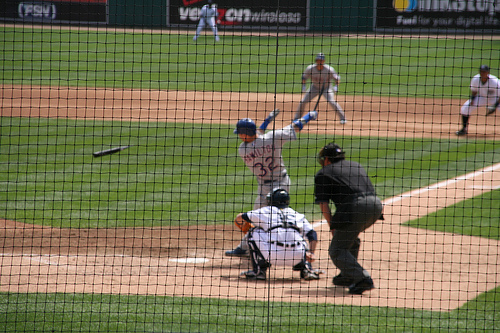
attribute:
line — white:
[365, 150, 499, 217]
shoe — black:
[331, 269, 352, 287]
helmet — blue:
[234, 116, 255, 134]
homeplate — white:
[161, 247, 215, 273]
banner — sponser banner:
[166, 0, 311, 31]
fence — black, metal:
[1, 1, 492, 323]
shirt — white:
[248, 206, 310, 251]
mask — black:
[265, 184, 289, 205]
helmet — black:
[266, 186, 289, 208]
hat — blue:
[232, 117, 256, 137]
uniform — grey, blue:
[291, 62, 346, 121]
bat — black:
[89, 137, 127, 161]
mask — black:
[312, 149, 332, 165]